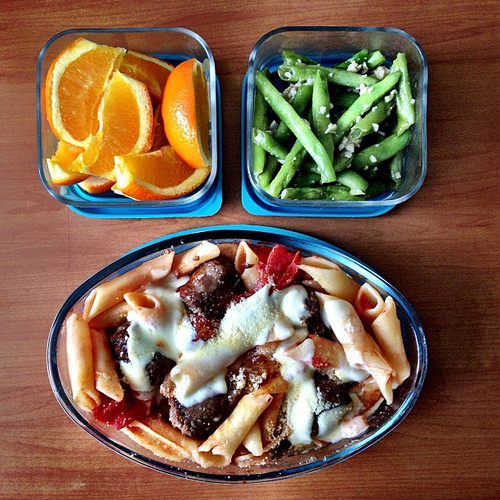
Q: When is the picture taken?
A: Daytime.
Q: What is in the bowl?
A: Food.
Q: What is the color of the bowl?
A: Blue.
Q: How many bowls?
A: 3.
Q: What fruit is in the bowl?
A: Orange.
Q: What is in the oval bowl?
A: Pasta.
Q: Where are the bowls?
A: In the table.